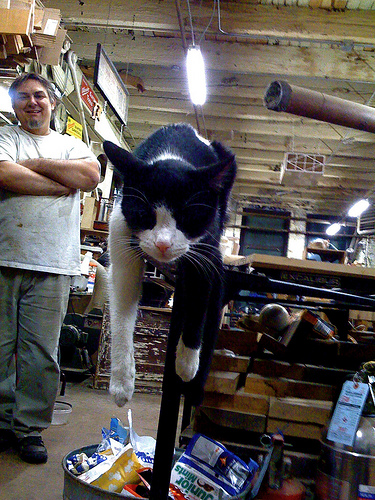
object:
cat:
[97, 112, 241, 410]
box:
[60, 440, 252, 499]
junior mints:
[168, 434, 259, 500]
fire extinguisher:
[311, 359, 375, 500]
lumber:
[267, 394, 332, 429]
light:
[184, 45, 207, 107]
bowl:
[50, 396, 73, 429]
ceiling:
[38, 0, 375, 206]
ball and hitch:
[258, 301, 315, 361]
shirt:
[0, 122, 102, 278]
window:
[238, 206, 291, 262]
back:
[226, 198, 374, 266]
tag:
[325, 378, 369, 450]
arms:
[0, 125, 72, 197]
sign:
[92, 41, 133, 128]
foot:
[108, 368, 136, 409]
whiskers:
[181, 255, 200, 276]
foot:
[174, 345, 202, 381]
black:
[183, 283, 208, 345]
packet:
[166, 431, 258, 499]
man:
[0, 73, 101, 466]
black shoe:
[11, 420, 50, 467]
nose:
[153, 234, 173, 256]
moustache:
[22, 107, 45, 131]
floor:
[0, 382, 184, 500]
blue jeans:
[0, 266, 71, 440]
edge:
[222, 251, 375, 281]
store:
[0, 0, 375, 500]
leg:
[107, 206, 144, 409]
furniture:
[148, 254, 374, 500]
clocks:
[50, 100, 71, 136]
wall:
[79, 110, 129, 197]